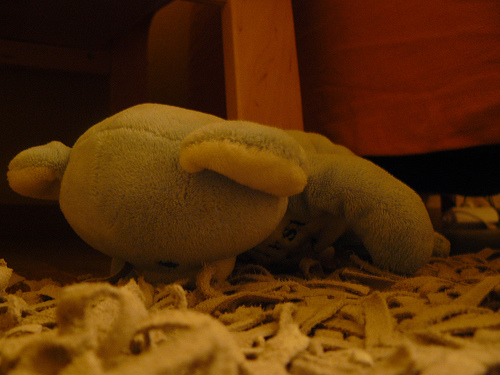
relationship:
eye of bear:
[160, 255, 179, 272] [80, 146, 231, 231]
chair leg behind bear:
[206, 22, 298, 110] [80, 146, 231, 231]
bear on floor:
[80, 146, 231, 231] [261, 295, 306, 325]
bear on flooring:
[80, 146, 231, 231] [367, 283, 391, 300]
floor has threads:
[261, 295, 306, 325] [13, 264, 48, 284]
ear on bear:
[204, 138, 289, 189] [80, 146, 231, 231]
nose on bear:
[155, 280, 195, 291] [80, 146, 231, 231]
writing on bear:
[279, 228, 305, 253] [80, 146, 231, 231]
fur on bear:
[240, 123, 315, 164] [80, 146, 231, 231]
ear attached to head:
[204, 138, 289, 189] [87, 95, 189, 177]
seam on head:
[135, 126, 186, 156] [87, 95, 189, 177]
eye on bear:
[160, 255, 179, 272] [80, 146, 231, 231]